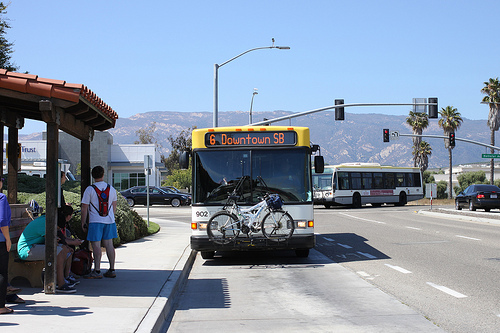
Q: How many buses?
A: 2.